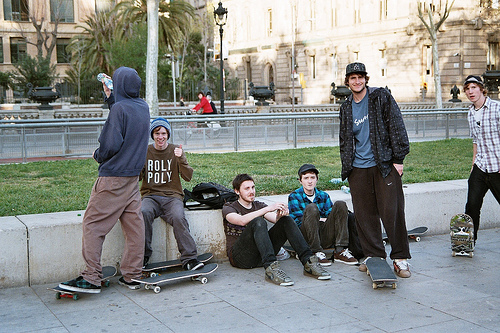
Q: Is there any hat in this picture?
A: Yes, there is a hat.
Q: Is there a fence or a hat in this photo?
A: Yes, there is a hat.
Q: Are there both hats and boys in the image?
A: Yes, there are both a hat and a boy.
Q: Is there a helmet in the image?
A: No, there are no helmets.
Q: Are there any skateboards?
A: Yes, there is a skateboard.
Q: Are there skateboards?
A: Yes, there is a skateboard.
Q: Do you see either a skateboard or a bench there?
A: Yes, there is a skateboard.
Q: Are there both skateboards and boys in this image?
A: Yes, there are both a skateboard and a boy.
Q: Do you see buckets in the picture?
A: No, there are no buckets.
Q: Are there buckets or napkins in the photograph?
A: No, there are no buckets or napkins.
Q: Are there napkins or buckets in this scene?
A: No, there are no buckets or napkins.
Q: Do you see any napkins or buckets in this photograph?
A: No, there are no buckets or napkins.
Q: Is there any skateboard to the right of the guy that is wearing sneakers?
A: Yes, there is a skateboard to the right of the guy.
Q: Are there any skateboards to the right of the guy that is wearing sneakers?
A: Yes, there is a skateboard to the right of the guy.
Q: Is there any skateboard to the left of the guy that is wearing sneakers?
A: No, the skateboard is to the right of the guy.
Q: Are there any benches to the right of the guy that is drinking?
A: No, there is a skateboard to the right of the guy.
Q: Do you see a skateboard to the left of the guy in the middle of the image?
A: Yes, there is a skateboard to the left of the guy.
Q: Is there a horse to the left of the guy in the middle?
A: No, there is a skateboard to the left of the guy.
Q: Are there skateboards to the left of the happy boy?
A: Yes, there is a skateboard to the left of the boy.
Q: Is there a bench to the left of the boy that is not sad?
A: No, there is a skateboard to the left of the boy.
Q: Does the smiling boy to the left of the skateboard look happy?
A: Yes, the boy is happy.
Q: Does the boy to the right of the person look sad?
A: No, the boy is happy.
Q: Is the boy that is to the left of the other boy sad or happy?
A: The boy is happy.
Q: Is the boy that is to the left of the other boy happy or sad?
A: The boy is happy.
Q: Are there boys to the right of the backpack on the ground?
A: Yes, there is a boy to the right of the backpack.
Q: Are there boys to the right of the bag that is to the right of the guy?
A: Yes, there is a boy to the right of the backpack.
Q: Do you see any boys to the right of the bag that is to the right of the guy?
A: Yes, there is a boy to the right of the backpack.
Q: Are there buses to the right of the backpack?
A: No, there is a boy to the right of the backpack.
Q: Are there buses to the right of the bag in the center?
A: No, there is a boy to the right of the backpack.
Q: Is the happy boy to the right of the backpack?
A: Yes, the boy is to the right of the backpack.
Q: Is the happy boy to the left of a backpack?
A: No, the boy is to the right of a backpack.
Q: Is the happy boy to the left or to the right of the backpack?
A: The boy is to the right of the backpack.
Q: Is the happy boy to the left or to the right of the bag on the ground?
A: The boy is to the right of the backpack.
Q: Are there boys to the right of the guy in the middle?
A: Yes, there is a boy to the right of the guy.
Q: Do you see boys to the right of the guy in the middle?
A: Yes, there is a boy to the right of the guy.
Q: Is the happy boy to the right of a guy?
A: Yes, the boy is to the right of a guy.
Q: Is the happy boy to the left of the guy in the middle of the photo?
A: No, the boy is to the right of the guy.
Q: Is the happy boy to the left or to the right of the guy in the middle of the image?
A: The boy is to the right of the guy.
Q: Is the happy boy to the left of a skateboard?
A: No, the boy is to the right of a skateboard.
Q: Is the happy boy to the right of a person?
A: Yes, the boy is to the right of a person.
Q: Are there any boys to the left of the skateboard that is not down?
A: Yes, there is a boy to the left of the skateboard.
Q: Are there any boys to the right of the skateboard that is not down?
A: No, the boy is to the left of the skateboard.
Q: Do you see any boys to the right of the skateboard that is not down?
A: No, the boy is to the left of the skateboard.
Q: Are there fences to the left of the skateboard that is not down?
A: No, there is a boy to the left of the skateboard.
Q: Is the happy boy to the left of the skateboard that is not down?
A: Yes, the boy is to the left of the skateboard.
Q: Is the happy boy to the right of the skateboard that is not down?
A: No, the boy is to the left of the skateboard.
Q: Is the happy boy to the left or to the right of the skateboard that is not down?
A: The boy is to the left of the skateboard.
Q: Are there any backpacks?
A: Yes, there is a backpack.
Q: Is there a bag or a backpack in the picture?
A: Yes, there is a backpack.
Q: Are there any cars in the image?
A: No, there are no cars.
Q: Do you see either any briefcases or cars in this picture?
A: No, there are no cars or briefcases.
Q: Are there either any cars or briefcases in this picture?
A: No, there are no cars or briefcases.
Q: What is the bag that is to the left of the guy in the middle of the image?
A: The bag is a backpack.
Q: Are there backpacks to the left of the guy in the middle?
A: Yes, there is a backpack to the left of the guy.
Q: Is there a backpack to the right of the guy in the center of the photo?
A: No, the backpack is to the left of the guy.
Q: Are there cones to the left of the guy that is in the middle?
A: No, there is a backpack to the left of the guy.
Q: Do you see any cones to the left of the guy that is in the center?
A: No, there is a backpack to the left of the guy.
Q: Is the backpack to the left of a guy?
A: Yes, the backpack is to the left of a guy.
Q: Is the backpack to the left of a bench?
A: No, the backpack is to the left of a guy.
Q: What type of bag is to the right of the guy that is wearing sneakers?
A: The bag is a backpack.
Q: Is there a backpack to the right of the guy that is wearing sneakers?
A: Yes, there is a backpack to the right of the guy.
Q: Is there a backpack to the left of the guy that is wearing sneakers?
A: No, the backpack is to the right of the guy.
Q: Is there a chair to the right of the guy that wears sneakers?
A: No, there is a backpack to the right of the guy.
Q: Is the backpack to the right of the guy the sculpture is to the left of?
A: Yes, the backpack is to the right of the guy.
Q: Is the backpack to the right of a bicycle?
A: No, the backpack is to the right of the guy.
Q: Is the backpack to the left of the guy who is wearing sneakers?
A: No, the backpack is to the right of the guy.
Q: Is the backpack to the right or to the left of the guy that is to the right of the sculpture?
A: The backpack is to the right of the guy.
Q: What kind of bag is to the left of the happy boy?
A: The bag is a backpack.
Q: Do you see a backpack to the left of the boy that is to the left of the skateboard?
A: Yes, there is a backpack to the left of the boy.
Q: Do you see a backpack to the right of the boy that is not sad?
A: No, the backpack is to the left of the boy.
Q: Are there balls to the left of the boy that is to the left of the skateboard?
A: No, there is a backpack to the left of the boy.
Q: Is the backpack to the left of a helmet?
A: No, the backpack is to the left of the boy.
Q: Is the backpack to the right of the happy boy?
A: No, the backpack is to the left of the boy.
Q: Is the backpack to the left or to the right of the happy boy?
A: The backpack is to the left of the boy.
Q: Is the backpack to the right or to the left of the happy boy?
A: The backpack is to the left of the boy.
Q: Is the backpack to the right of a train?
A: No, the backpack is to the right of a boy.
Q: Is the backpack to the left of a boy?
A: No, the backpack is to the right of a boy.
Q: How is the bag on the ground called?
A: The bag is a backpack.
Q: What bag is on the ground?
A: The bag is a backpack.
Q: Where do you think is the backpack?
A: The backpack is on the ground.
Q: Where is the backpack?
A: The backpack is on the ground.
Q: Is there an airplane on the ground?
A: No, there is a backpack on the ground.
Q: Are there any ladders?
A: No, there are no ladders.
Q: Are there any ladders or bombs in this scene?
A: No, there are no ladders or bombs.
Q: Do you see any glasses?
A: No, there are no glasses.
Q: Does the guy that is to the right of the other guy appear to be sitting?
A: Yes, the guy is sitting.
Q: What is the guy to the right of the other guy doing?
A: The guy is sitting.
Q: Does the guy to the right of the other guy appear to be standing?
A: No, the guy is sitting.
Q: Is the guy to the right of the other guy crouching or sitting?
A: The guy is sitting.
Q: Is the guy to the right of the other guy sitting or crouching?
A: The guy is sitting.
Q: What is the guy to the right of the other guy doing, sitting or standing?
A: The guy is sitting.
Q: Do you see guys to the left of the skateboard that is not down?
A: Yes, there is a guy to the left of the skateboard.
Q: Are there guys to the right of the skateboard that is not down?
A: No, the guy is to the left of the skateboard.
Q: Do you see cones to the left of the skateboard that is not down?
A: No, there is a guy to the left of the skateboard.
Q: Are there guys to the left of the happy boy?
A: Yes, there is a guy to the left of the boy.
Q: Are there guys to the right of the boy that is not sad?
A: No, the guy is to the left of the boy.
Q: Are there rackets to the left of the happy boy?
A: No, there is a guy to the left of the boy.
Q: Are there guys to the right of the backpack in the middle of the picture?
A: Yes, there is a guy to the right of the backpack.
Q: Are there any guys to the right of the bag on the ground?
A: Yes, there is a guy to the right of the backpack.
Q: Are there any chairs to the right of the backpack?
A: No, there is a guy to the right of the backpack.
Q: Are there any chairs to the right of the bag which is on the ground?
A: No, there is a guy to the right of the backpack.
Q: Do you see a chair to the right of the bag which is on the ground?
A: No, there is a guy to the right of the backpack.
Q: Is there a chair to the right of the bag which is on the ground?
A: No, there is a guy to the right of the backpack.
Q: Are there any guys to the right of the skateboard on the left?
A: Yes, there is a guy to the right of the skateboard.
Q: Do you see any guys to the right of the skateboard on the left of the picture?
A: Yes, there is a guy to the right of the skateboard.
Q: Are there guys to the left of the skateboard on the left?
A: No, the guy is to the right of the skateboard.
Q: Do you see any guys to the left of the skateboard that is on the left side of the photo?
A: No, the guy is to the right of the skateboard.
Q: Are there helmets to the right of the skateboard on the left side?
A: No, there is a guy to the right of the skateboard.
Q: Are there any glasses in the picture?
A: No, there are no glasses.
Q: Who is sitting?
A: The guy is sitting.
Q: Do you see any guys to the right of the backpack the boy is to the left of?
A: Yes, there is a guy to the right of the backpack.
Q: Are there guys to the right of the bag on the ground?
A: Yes, there is a guy to the right of the backpack.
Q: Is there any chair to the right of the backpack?
A: No, there is a guy to the right of the backpack.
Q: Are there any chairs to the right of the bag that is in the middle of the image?
A: No, there is a guy to the right of the backpack.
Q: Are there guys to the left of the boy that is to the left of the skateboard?
A: Yes, there is a guy to the left of the boy.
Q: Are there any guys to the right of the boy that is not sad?
A: No, the guy is to the left of the boy.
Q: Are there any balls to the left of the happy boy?
A: No, there is a guy to the left of the boy.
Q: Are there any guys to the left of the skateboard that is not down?
A: Yes, there is a guy to the left of the skateboard.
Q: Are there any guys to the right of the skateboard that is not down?
A: No, the guy is to the left of the skateboard.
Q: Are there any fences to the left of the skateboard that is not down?
A: No, there is a guy to the left of the skateboard.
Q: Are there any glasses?
A: No, there are no glasses.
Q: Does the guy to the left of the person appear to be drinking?
A: Yes, the guy is drinking.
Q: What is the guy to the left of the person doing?
A: The guy is drinking.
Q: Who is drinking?
A: The guy is drinking.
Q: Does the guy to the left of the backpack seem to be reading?
A: No, the guy is drinking.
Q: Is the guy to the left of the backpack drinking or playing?
A: The guy is drinking.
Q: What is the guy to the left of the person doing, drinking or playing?
A: The guy is drinking.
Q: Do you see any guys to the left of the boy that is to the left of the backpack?
A: Yes, there is a guy to the left of the boy.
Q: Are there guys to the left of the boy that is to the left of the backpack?
A: Yes, there is a guy to the left of the boy.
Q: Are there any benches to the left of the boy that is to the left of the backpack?
A: No, there is a guy to the left of the boy.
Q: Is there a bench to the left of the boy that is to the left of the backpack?
A: No, there is a guy to the left of the boy.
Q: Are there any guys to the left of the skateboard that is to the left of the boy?
A: Yes, there is a guy to the left of the skateboard.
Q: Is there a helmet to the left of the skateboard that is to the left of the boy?
A: No, there is a guy to the left of the skateboard.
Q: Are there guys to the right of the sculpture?
A: Yes, there is a guy to the right of the sculpture.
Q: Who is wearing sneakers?
A: The guy is wearing sneakers.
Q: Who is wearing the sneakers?
A: The guy is wearing sneakers.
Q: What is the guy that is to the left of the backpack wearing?
A: The guy is wearing sneakers.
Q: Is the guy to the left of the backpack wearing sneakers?
A: Yes, the guy is wearing sneakers.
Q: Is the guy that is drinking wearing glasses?
A: No, the guy is wearing sneakers.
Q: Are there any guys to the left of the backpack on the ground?
A: Yes, there is a guy to the left of the backpack.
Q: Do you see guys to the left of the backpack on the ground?
A: Yes, there is a guy to the left of the backpack.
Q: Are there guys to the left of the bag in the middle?
A: Yes, there is a guy to the left of the backpack.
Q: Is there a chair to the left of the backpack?
A: No, there is a guy to the left of the backpack.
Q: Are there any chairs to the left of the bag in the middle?
A: No, there is a guy to the left of the backpack.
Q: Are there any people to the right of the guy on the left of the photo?
A: Yes, there is a person to the right of the guy.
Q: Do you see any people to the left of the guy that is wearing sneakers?
A: No, the person is to the right of the guy.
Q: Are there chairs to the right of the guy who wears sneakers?
A: No, there is a person to the right of the guy.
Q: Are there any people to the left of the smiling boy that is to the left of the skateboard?
A: Yes, there is a person to the left of the boy.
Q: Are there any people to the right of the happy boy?
A: No, the person is to the left of the boy.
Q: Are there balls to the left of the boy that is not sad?
A: No, there is a person to the left of the boy.